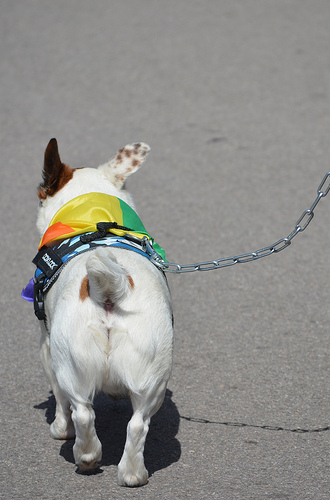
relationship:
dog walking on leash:
[34, 137, 174, 485] [22, 206, 242, 312]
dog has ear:
[34, 137, 174, 485] [95, 140, 151, 189]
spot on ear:
[132, 140, 141, 150] [95, 140, 151, 189]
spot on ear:
[119, 140, 141, 174] [95, 140, 151, 189]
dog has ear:
[34, 137, 174, 485] [69, 120, 184, 180]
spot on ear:
[119, 140, 141, 174] [69, 120, 184, 180]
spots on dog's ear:
[131, 157, 139, 166] [101, 139, 150, 188]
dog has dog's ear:
[34, 137, 174, 485] [101, 139, 150, 188]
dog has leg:
[34, 137, 174, 485] [116, 389, 166, 488]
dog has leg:
[34, 137, 174, 485] [55, 371, 103, 473]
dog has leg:
[34, 137, 174, 485] [56, 380, 102, 473]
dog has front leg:
[34, 137, 174, 485] [29, 329, 78, 436]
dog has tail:
[34, 137, 174, 485] [83, 246, 131, 309]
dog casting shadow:
[30, 189, 197, 446] [71, 396, 189, 476]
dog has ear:
[34, 137, 174, 485] [25, 134, 81, 195]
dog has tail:
[34, 137, 174, 485] [84, 247, 129, 303]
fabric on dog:
[20, 190, 165, 301] [34, 137, 174, 485]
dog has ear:
[34, 137, 174, 485] [36, 132, 78, 195]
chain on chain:
[163, 172, 329, 275] [163, 172, 328, 274]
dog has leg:
[34, 137, 174, 485] [37, 338, 73, 438]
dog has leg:
[34, 137, 174, 485] [70, 404, 103, 471]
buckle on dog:
[27, 285, 46, 316] [34, 137, 174, 485]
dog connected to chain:
[34, 137, 174, 485] [140, 168, 329, 275]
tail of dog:
[82, 246, 138, 314] [34, 137, 174, 485]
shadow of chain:
[176, 412, 329, 440] [119, 166, 328, 274]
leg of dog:
[113, 381, 162, 488] [34, 137, 174, 485]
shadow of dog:
[32, 383, 182, 476] [34, 137, 174, 485]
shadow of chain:
[176, 412, 329, 440] [140, 168, 329, 275]